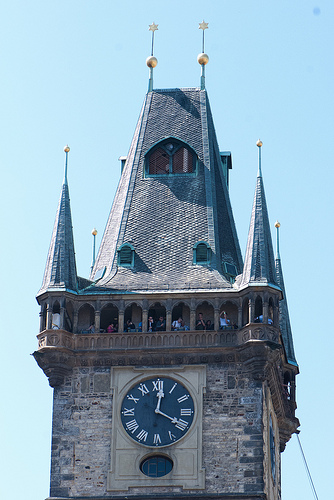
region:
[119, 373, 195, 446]
analog clock on clock tower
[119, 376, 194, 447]
gold and black details on clock face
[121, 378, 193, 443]
roman numerals on clock face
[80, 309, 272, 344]
group of people looking out over clock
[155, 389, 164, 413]
hour hand on clock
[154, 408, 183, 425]
gold hand on clock face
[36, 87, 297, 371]
blue shingles on roof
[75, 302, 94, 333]
open arched window on building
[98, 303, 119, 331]
open arched window on building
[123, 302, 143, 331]
open arched window on building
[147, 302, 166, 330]
open arched window on building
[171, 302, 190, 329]
open arched window on building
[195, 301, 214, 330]
open arched window on building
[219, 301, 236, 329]
open arched window on building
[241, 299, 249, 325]
open arched window on building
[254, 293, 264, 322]
open arched window on building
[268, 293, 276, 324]
open arched window on building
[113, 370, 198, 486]
the clock on a clock tour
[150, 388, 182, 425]
hands on a black clock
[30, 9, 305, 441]
steeples atop of a church tower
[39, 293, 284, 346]
windows with statues in them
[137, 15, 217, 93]
star topped poles above a building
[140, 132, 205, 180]
the top window of a clock tower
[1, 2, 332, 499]
a tower on a sunny blue day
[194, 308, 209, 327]
a statue in a clock tower display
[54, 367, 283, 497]
brick section on a clock tower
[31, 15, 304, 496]
a gothic tower from the past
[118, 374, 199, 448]
black face on clock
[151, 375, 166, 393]
white number on clock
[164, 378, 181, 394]
white number on clock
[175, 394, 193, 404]
white number on clock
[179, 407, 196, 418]
white number on clock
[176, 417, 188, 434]
white number on clock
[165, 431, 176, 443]
white number on clock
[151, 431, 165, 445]
white number on clock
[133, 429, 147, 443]
white number on clock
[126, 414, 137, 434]
white number on clock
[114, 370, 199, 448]
large clock on clock tower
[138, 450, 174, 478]
oval window beneath clock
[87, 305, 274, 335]
people looking out from top of tower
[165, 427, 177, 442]
roman numeral five on clock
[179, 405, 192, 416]
roman numeral three on clock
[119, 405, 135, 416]
roman numeral nine on clock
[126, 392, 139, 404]
roman numeral ten on clock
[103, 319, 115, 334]
person wearing a pink shrit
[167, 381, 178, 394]
roman numeral one on clock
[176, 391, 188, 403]
roman numeral two on clock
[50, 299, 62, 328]
arched opening at top of tower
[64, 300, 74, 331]
arched opening at top of tower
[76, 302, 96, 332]
arched opening at top of tower